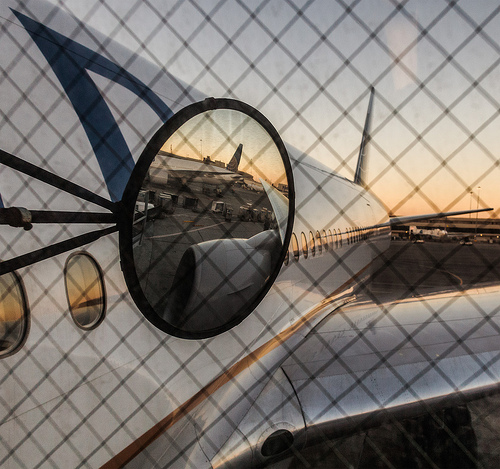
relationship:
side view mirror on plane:
[117, 93, 294, 341] [14, 17, 489, 467]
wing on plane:
[221, 279, 499, 456] [14, 17, 489, 467]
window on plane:
[61, 249, 112, 329] [14, 17, 489, 467]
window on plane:
[288, 231, 301, 263] [14, 17, 489, 467]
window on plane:
[300, 231, 310, 261] [14, 17, 489, 467]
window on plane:
[309, 230, 317, 258] [14, 17, 489, 467]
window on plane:
[315, 231, 324, 253] [14, 17, 489, 467]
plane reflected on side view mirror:
[142, 141, 251, 189] [117, 93, 294, 341]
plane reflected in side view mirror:
[142, 141, 251, 189] [117, 93, 294, 341]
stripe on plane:
[19, 240, 390, 468] [14, 17, 489, 467]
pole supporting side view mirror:
[0, 139, 121, 210] [117, 93, 294, 341]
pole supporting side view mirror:
[0, 203, 121, 230] [117, 93, 294, 341]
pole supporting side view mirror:
[0, 225, 131, 275] [117, 93, 294, 341]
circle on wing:
[260, 428, 295, 457] [221, 279, 499, 456]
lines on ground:
[414, 247, 499, 293] [380, 240, 497, 289]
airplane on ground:
[407, 225, 452, 245] [408, 240, 454, 257]